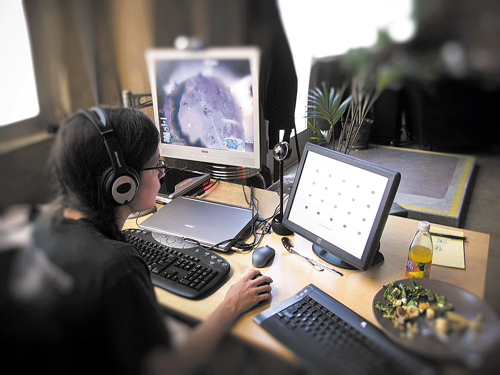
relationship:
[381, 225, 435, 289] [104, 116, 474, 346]
beverage on desk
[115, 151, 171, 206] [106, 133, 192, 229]
glass on face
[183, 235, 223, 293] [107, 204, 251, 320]
pad on keyboard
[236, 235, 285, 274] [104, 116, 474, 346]
mouse on desk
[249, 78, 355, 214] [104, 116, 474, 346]
plant on desk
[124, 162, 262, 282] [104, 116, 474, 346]
laptop on desk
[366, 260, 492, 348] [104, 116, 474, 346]
food on desk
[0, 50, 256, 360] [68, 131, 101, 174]
woman has hair